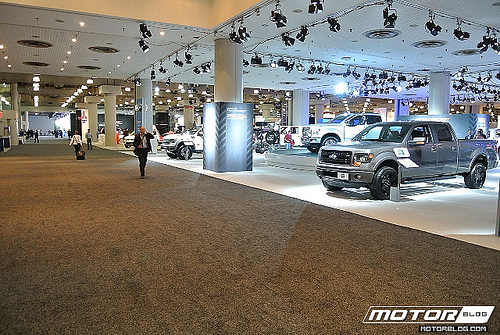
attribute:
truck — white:
[300, 110, 386, 155]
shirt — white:
[68, 134, 87, 145]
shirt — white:
[140, 134, 148, 147]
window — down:
[406, 123, 430, 143]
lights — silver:
[35, 14, 100, 74]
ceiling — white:
[6, 13, 164, 123]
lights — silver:
[39, 17, 133, 155]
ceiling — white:
[14, 6, 185, 122]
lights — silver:
[38, 20, 145, 143]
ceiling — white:
[23, 14, 147, 152]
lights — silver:
[22, 0, 127, 147]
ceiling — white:
[42, 14, 482, 173]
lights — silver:
[34, 2, 123, 122]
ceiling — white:
[29, 18, 390, 140]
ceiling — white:
[27, 20, 359, 104]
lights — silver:
[45, 17, 129, 144]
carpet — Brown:
[27, 124, 452, 331]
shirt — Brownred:
[276, 126, 303, 143]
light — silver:
[273, 10, 289, 30]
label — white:
[386, 144, 424, 176]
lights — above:
[226, 17, 411, 82]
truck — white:
[350, 99, 480, 193]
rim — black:
[373, 164, 398, 193]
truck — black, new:
[306, 114, 496, 203]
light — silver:
[135, 19, 158, 59]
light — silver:
[232, 14, 253, 46]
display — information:
[391, 143, 419, 187]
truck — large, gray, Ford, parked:
[314, 118, 484, 203]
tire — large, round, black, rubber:
[367, 162, 397, 200]